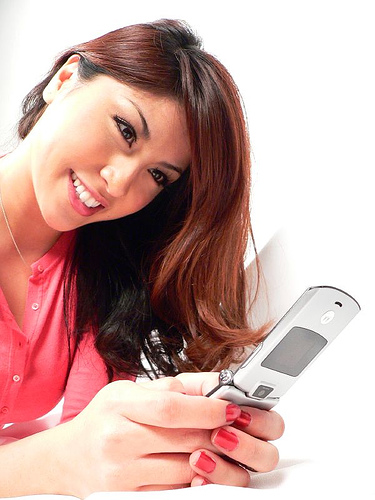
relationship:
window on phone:
[260, 328, 328, 376] [187, 282, 368, 429]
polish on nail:
[195, 452, 216, 473] [196, 449, 214, 474]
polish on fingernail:
[211, 429, 239, 450] [212, 428, 238, 455]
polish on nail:
[222, 405, 240, 420] [199, 477, 208, 483]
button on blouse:
[29, 297, 43, 310] [1, 221, 143, 438]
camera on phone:
[250, 382, 271, 401] [203, 279, 362, 412]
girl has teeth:
[0, 16, 286, 500] [84, 197, 95, 208]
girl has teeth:
[0, 16, 286, 500] [78, 189, 91, 204]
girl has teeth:
[0, 16, 286, 500] [75, 184, 87, 195]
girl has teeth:
[0, 16, 286, 500] [72, 178, 80, 189]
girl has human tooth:
[0, 16, 286, 500] [69, 169, 101, 211]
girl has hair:
[0, 16, 286, 500] [17, 22, 278, 377]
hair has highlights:
[17, 22, 278, 377] [201, 78, 240, 305]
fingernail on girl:
[225, 401, 251, 433] [0, 16, 286, 500]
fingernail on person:
[225, 401, 251, 433] [2, 17, 282, 498]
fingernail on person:
[212, 428, 238, 455] [2, 17, 282, 498]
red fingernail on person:
[192, 450, 222, 473] [3, 31, 313, 491]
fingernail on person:
[212, 428, 238, 455] [3, 31, 313, 491]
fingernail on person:
[199, 394, 256, 434] [2, 17, 282, 498]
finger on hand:
[127, 372, 285, 489] [75, 385, 243, 490]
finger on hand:
[128, 383, 244, 436] [43, 373, 249, 496]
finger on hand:
[127, 372, 285, 489] [214, 415, 294, 498]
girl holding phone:
[0, 16, 286, 497] [203, 279, 362, 412]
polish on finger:
[195, 452, 216, 473] [187, 449, 249, 487]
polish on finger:
[211, 429, 238, 452] [209, 425, 278, 472]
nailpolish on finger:
[235, 408, 251, 427] [231, 404, 284, 439]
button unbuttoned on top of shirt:
[35, 262, 45, 272] [7, 221, 135, 461]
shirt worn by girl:
[7, 233, 134, 438] [0, 16, 286, 497]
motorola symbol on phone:
[319, 309, 336, 325] [195, 265, 373, 426]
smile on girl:
[71, 169, 108, 216] [0, 16, 286, 497]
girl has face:
[0, 16, 286, 497] [35, 78, 186, 239]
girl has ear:
[0, 16, 286, 497] [40, 54, 81, 104]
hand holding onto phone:
[76, 371, 285, 500] [202, 281, 361, 428]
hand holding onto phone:
[176, 371, 284, 491] [202, 281, 361, 428]